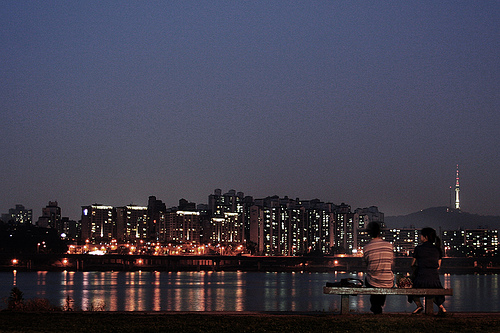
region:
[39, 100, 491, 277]
two people watching the skyline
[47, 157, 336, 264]
a city skyline at night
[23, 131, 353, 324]
the city is on the water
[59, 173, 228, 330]
lights reflecting off water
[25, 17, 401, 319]
time is just after sunset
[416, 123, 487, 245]
a white tower in background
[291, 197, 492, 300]
man and woman on bench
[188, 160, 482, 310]
a couple looking at the city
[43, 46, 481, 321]
a romantic date night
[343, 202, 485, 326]
they have dark hair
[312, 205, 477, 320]
two people sitting on a bench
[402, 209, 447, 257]
a woman with her hair in a ponytail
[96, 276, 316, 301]
a body of water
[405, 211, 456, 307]
a woman sitting on a bench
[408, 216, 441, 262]
a woman with black hair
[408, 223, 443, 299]
a woman wearing black clothing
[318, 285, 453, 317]
a concrete bench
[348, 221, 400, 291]
a man sitting on a bench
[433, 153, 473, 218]
a tall building with lights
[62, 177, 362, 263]
several buildings in a row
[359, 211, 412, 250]
the head of a man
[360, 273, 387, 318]
the legs of a man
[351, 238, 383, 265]
the shoulder of a man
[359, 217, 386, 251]
the hair of a man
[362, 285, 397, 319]
a man wearing shoes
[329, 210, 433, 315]
a man wearing a shirt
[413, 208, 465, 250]
the head of a woman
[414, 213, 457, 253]
the hair of a woman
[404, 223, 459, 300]
a woman sitting on a bench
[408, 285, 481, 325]
the feet of a woman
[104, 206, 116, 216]
bright light on building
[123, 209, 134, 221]
bright light on building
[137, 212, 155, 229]
bright light on building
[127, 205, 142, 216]
bright light on building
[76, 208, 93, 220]
bright light on building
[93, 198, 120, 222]
bright light on building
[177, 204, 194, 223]
bright light on building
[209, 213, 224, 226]
bright light on building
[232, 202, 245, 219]
bright light on building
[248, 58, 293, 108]
white clouds in blue sky